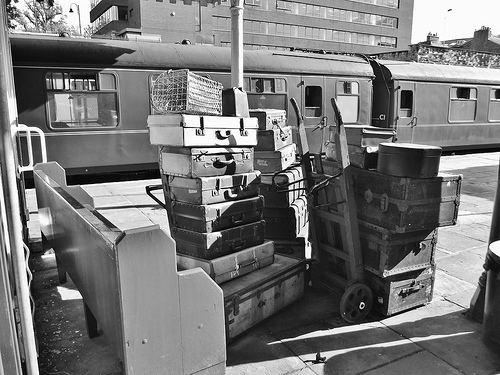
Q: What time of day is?
A: Daytime.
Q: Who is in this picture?
A: No one.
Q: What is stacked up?
A: Luggage.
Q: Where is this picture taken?
A: Train stattion.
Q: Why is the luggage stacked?
A: Organization.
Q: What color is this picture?
A: Black and white.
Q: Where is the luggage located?
A: Near the bench.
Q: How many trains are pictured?
A: One.